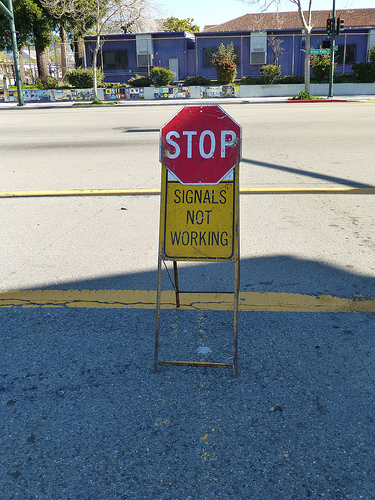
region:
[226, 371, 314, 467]
Object on a street.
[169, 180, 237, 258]
Black letters that say signals not working.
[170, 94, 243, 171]
Red and white sign.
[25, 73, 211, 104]
Colorful art on wall .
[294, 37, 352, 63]
Green and white street sign.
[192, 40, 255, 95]
Green bush with maroon flowers.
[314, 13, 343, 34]
Traffic signal that is green.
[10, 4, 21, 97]
Silver traffic pole.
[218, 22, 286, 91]
Window on a house.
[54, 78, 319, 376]
Traffic sign on a street.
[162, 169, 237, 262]
The yellow and black sign below the stop sign.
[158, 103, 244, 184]
The stop sign above the yellow and black sign.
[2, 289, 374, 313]
The yellow line on the street directly behind the signs.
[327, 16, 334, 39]
The traffic light facing directly straight.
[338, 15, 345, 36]
The traffic light facing towards the right.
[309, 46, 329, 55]
The green street sign nearest to the tree.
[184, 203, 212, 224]
The word NOT on the yellow and black sign.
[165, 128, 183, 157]
The letter S on the stop sign.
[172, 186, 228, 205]
The word Signals on the yellow and black sign.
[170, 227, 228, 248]
The word Working on the yellow and black sign.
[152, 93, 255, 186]
the sign is red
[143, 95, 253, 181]
the sign says stop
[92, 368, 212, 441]
the ground is gray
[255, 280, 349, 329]
the strip is yellow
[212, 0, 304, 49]
the roof is brown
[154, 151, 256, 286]
the sign is yellow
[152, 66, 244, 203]
the sign is octagon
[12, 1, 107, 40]
the tree is green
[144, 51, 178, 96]
the bush is green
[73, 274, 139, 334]
the cement is cracked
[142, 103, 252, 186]
a red and white stop sing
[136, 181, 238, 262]
a yellow traffic sign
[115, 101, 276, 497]
two traffic signs on a metal stand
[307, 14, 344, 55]
a traffic light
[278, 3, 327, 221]
a tree growing beside a roadway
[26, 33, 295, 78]
a tall metal fence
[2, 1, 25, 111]
a traffic light on a green pole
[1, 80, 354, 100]
a cement wall with several stickers on it.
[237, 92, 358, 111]
a curb with part painted red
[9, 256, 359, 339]
a yellow line painted on a road way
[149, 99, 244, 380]
Road sign in street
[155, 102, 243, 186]
The sign says stop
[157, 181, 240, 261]
The sign says signals not working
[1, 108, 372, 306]
The street is in the middle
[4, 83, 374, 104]
Retaining wall is covered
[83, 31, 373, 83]
Building is painted blue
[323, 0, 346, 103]
The stoplight is green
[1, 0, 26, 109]
The stoplight has three colors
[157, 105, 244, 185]
Stop sign is red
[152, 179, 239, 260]
Caution sign is yellow